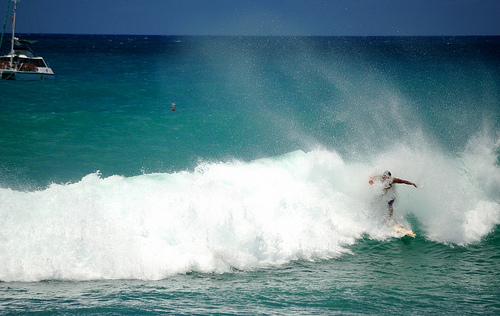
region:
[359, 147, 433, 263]
A surfer in the water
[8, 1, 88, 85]
a boat on the water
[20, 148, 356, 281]
a larger white wave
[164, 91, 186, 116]
a float in the water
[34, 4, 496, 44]
a clear blue sky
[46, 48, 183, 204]
greenish blue white water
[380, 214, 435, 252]
a surf board in the water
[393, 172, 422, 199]
a persons right arm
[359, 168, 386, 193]
a person's left arm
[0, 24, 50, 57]
a green flag on the boat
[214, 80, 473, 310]
a person surfing in the water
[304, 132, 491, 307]
a person on a surfboard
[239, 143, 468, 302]
a person on a surfboard in the water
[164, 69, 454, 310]
a person riding a wave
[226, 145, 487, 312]
a person surfing a wave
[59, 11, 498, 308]
a body of water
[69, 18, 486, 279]
a body of water with a surfer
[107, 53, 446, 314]
a body of water with a wave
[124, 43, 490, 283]
a body of water with someone surfing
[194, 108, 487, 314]
a surfer in a body of water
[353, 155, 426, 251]
surfer in the middle of a breaking wave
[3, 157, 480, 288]
ocean wave breaking against the shore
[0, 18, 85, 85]
a boat out in the ocean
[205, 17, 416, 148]
spray coming off of the ocean waves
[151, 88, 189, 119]
floating buoy in the water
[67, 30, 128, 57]
dark blue ocean water on the horizon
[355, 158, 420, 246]
surfer riding his board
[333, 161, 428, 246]
emerging wave rider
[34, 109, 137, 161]
blue-green tinted ocean water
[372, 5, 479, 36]
blue, clear sky on the horizon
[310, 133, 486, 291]
This is a picture of a man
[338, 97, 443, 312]
This is a surfer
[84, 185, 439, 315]
These are waves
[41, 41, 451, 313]
This is a beach scene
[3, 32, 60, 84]
This is a white boat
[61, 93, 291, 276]
The ocean is teal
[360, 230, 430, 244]
This is a surfboard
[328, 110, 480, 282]
The person is on the waves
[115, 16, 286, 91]
The sky is medium blue color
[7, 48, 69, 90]
This is a fishing boat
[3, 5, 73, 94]
A small white boat in the ocean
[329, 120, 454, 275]
A man surfing in the blue ocean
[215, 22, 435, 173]
A thin mist of water spraying into the air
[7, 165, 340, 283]
Large amounts of white sea foam on the wave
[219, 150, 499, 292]
A large wave under the surfer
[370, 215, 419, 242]
A yellow surfboard on the big wave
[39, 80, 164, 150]
The water looks calm behind the wave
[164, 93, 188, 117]
A small buoy floating in the water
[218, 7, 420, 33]
The sky looks clear and blue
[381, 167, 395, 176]
The man's hair is short